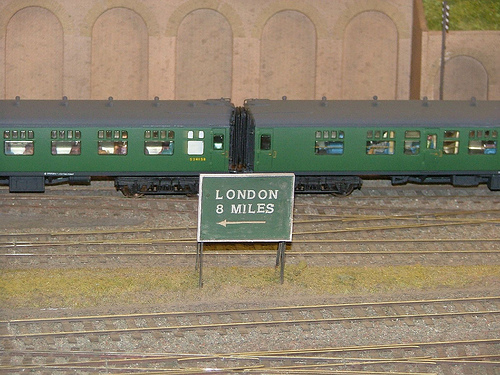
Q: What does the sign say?
A: London 8 miles.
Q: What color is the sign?
A: Green.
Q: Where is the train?
A: On the tracks.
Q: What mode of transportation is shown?
A: A train.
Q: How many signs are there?
A: 1.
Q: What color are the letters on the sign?
A: White.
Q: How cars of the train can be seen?
A: 2.